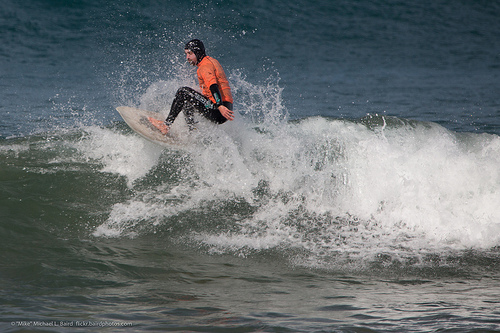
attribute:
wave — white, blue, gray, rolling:
[2, 109, 499, 278]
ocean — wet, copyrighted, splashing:
[2, 2, 500, 333]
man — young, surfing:
[144, 38, 237, 140]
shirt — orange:
[192, 55, 235, 109]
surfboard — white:
[112, 103, 192, 154]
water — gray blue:
[2, 3, 498, 131]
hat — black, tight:
[184, 37, 207, 65]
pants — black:
[163, 85, 233, 136]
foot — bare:
[145, 111, 173, 138]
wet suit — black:
[165, 37, 234, 133]